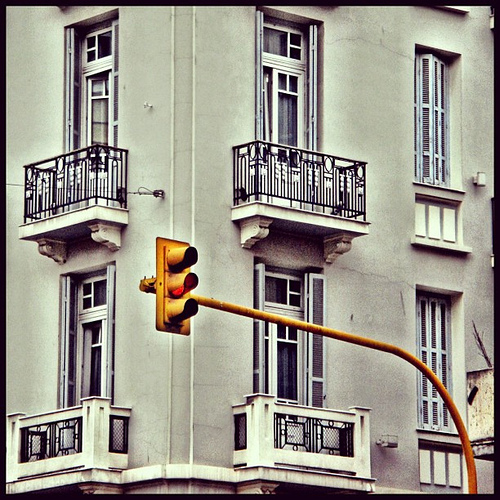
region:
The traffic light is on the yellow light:
[149, 259, 214, 354]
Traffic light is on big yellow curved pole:
[129, 221, 472, 462]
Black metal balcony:
[231, 138, 378, 208]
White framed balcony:
[231, 408, 406, 490]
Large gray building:
[17, 133, 477, 444]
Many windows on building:
[32, 222, 473, 464]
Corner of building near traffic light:
[71, 187, 261, 443]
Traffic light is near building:
[48, 197, 410, 412]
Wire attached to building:
[13, 176, 179, 211]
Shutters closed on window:
[419, 47, 451, 175]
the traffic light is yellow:
[125, 221, 483, 493]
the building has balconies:
[16, 3, 394, 305]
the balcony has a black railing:
[225, 6, 386, 283]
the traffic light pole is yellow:
[118, 223, 483, 496]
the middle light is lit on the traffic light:
[121, 216, 253, 370]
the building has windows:
[213, 5, 484, 290]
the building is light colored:
[8, 4, 499, 495]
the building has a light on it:
[356, 409, 422, 464]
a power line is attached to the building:
[4, 160, 184, 240]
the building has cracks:
[139, 98, 228, 461]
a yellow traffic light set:
[152, 235, 200, 340]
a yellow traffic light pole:
[134, 275, 482, 495]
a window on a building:
[261, 260, 303, 405]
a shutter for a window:
[304, 267, 328, 409]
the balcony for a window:
[229, 390, 379, 492]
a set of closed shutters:
[414, 283, 462, 436]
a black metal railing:
[228, 137, 370, 224]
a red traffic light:
[171, 276, 188, 296]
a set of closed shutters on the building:
[411, 45, 462, 194]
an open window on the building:
[80, 67, 117, 174]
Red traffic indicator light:
[156, 269, 195, 296]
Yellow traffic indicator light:
[145, 231, 205, 336]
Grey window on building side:
[230, 11, 390, 266]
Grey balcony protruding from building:
[23, 154, 133, 246]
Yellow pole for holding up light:
[190, 284, 497, 499]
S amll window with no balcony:
[412, 291, 481, 446]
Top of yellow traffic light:
[152, 233, 207, 279]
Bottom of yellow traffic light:
[147, 291, 209, 358]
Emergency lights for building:
[361, 413, 423, 468]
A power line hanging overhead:
[1, 182, 167, 198]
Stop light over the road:
[136, 233, 212, 333]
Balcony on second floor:
[228, 135, 386, 252]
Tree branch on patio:
[467, 324, 498, 370]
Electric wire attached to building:
[12, 179, 169, 207]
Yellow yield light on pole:
[164, 273, 209, 295]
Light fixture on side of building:
[374, 425, 418, 447]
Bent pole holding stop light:
[208, 289, 483, 474]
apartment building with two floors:
[10, 12, 485, 449]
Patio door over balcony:
[259, 62, 322, 143]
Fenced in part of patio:
[103, 413, 134, 461]